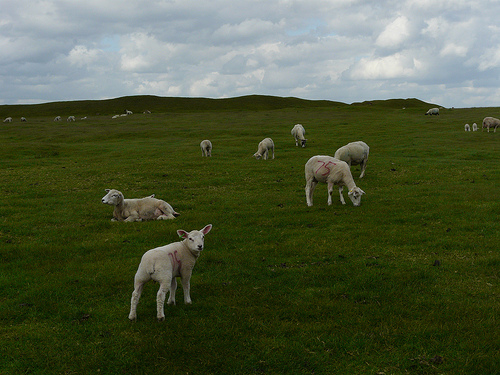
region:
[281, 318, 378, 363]
this is the grass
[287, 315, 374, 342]
the grass is green in colour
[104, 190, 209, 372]
these are the sheep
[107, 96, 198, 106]
this is the hill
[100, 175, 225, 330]
the sheep are white in colour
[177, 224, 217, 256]
this is the head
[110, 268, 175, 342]
these are the rear limbs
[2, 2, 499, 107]
Blue and white cloudy sky.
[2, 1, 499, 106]
Blue sky filled with white clouds.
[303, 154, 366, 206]
White grazing sheep with head down and 75 on side.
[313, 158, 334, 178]
Red 75 on sheeps side.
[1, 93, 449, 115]
Darker hillier green land under the sky.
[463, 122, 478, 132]
Two white rear ends of sheep to the left of a bigger one on the right.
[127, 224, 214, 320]
A whiter sheep looking at the camera.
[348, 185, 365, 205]
White head of a sheep with 75 on it.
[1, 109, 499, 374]
All the lighter green grass in a field.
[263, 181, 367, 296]
part of a field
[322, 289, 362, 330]
part of a filed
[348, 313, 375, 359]
part of a ground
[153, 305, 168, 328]
part fo a lreh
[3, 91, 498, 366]
Lot of sheep's standing in the forest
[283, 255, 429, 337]
Green color grass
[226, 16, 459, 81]
A blue color sky with clouds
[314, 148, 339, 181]
Some number written in the sheep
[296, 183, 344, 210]
Legs of the sheep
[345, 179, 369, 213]
Head of the sheep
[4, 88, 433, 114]
A small mountain near the forest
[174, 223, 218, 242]
Ears of the forest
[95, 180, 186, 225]
A sheep lying in the grass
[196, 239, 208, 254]
Black color nose and mouth of the sheep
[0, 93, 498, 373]
the large area of grass on the ground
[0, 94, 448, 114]
the hills in the distance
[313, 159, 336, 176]
the number 75 on the sheep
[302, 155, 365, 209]
the sheep with number 75 on it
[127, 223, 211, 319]
the sheep looking at the camera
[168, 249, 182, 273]
the red markings on the sheep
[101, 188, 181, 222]
the sheep lying on the grass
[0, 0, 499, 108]
the clouds in the sky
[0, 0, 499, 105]
the sky filled with clouds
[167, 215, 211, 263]
the head of a white lamb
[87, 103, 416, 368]
the sheep are grazing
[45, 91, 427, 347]
a small herd of sheep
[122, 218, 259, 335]
this sheep is looking at the camera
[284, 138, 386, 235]
the numer 75 is spray painted on the animal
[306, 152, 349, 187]
the number 75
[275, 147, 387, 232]
the numbers are red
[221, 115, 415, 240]
these sheep are grazing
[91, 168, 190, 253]
this sheep is sitting in the grass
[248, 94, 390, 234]
sheep grazing in the green grass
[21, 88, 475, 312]
a scene out in the field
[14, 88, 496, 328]
some livestock roam and graze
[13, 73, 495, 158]
some hills in the background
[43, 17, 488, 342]
a scene outside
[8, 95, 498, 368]
green grass on ground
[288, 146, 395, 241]
a sheep marked 75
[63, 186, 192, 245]
a sheep lying down